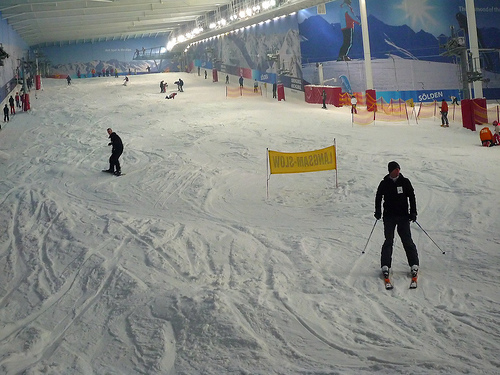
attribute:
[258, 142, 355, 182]
sign — yellow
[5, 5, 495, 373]
event — indoor, skiing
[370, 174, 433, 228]
jacket — black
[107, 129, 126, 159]
jacket — black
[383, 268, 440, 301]
skis — turned inward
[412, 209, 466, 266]
pole — skiing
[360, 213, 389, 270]
pole — skiing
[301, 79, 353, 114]
barrier — red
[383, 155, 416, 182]
beanie — black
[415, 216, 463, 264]
pole — ski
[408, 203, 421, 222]
hand — skier's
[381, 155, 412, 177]
hat — black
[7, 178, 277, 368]
trail — ski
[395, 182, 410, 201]
square — white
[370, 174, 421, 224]
coat — black, winter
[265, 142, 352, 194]
banner — yellow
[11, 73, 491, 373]
slope — snow, interior, inside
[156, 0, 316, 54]
lights — white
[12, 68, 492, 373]
hill — snow covered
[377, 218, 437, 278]
pants — black, snow, pair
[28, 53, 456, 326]
people — skiing, snowboarding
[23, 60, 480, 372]
people — snowboarding, skiing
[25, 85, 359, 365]
slope — indoor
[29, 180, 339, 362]
snow — indoor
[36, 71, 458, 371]
slope — inside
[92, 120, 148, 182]
he — snowboarding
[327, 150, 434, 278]
he — skiing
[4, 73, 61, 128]
they — lined up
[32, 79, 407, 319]
slope — inside, snowy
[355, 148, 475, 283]
person — snowboarding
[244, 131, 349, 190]
sign — yellow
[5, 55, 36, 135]
people — moving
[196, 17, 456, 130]
walls — winter 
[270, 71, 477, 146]
fence — yellow, mesh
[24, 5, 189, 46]
ceiling — white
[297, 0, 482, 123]
picture — large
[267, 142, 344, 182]
sign — yellow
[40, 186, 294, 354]
snow — marked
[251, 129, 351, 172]
sign — black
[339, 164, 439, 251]
man — holding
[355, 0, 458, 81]
wall — painted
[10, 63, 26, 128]
people — standing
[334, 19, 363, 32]
shirt — red